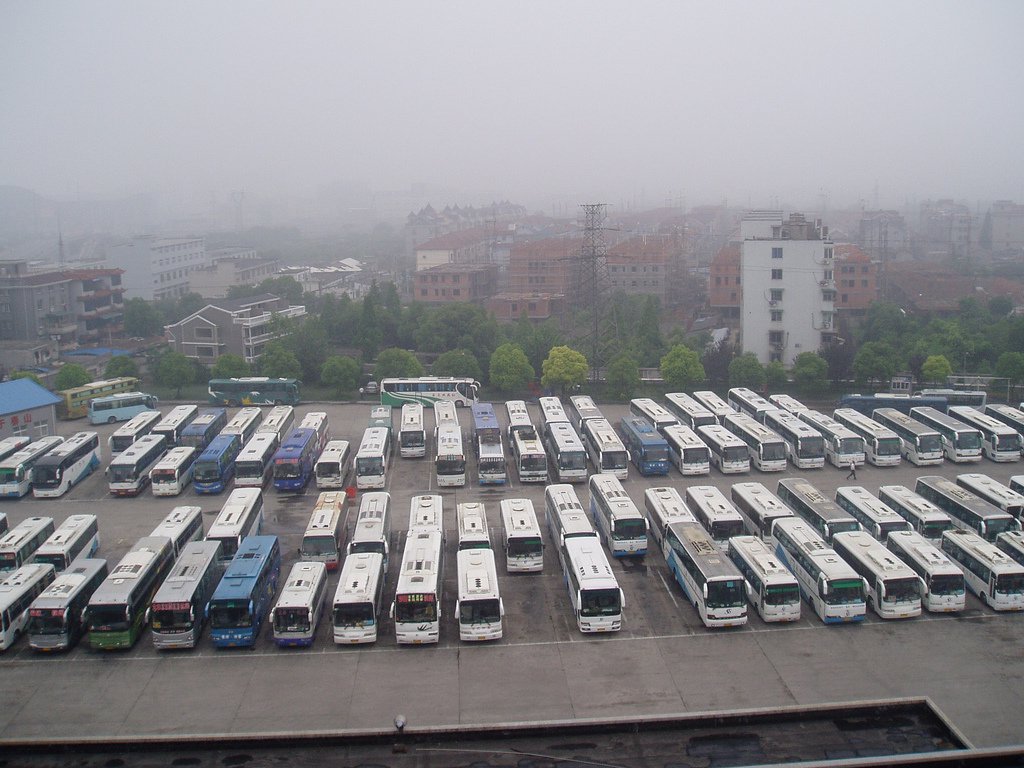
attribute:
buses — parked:
[17, 382, 1022, 673]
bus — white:
[556, 535, 640, 637]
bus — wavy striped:
[380, 369, 490, 404]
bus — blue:
[195, 520, 288, 657]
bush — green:
[348, 267, 418, 363]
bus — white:
[455, 544, 508, 648]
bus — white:
[558, 526, 630, 637]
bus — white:
[262, 556, 329, 650]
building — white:
[715, 201, 852, 396]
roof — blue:
[12, 370, 28, 409]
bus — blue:
[200, 526, 287, 645]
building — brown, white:
[161, 305, 248, 385]